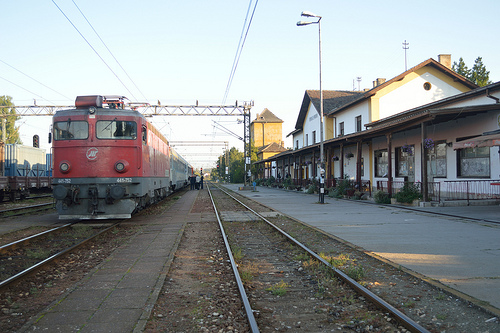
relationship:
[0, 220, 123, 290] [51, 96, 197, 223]
tracks are under train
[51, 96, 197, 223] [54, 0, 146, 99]
train underneath power lines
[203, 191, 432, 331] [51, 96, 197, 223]
tracks to right of train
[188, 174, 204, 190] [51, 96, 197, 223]
people next to train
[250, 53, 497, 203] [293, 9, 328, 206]
station next to light pole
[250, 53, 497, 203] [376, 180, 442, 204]
station behind railing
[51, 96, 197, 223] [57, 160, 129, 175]
train has headlights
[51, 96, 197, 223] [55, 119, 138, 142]
train has windows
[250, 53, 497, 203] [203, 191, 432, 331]
station near tracks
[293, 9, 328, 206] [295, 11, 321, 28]
light pole has lights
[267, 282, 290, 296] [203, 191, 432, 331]
grass near tracks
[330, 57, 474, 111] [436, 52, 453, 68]
roof has chimney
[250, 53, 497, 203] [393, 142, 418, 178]
station has window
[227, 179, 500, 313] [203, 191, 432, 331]
pavement beside tracks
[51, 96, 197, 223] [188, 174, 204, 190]
train next to people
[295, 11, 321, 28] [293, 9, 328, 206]
lights are on top of light pole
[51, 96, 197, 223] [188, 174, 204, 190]
train to left of people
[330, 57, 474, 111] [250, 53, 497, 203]
roof on top of station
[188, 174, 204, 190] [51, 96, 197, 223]
people are boarding train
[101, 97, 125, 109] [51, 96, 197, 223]
antenna on top of train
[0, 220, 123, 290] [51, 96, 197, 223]
tracks are underneath train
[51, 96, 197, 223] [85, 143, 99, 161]
train has logo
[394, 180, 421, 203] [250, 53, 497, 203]
bush next to station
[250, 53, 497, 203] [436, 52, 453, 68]
station has chimney